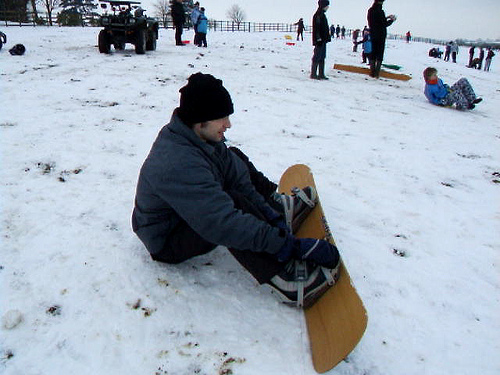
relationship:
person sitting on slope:
[312, 0, 344, 84] [5, 27, 495, 374]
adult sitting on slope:
[366, 0, 398, 81] [5, 27, 495, 374]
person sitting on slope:
[169, 2, 194, 48] [5, 27, 495, 374]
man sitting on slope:
[131, 70, 340, 310] [5, 27, 495, 374]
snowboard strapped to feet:
[261, 120, 380, 372] [269, 171, 338, 306]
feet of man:
[269, 171, 338, 306] [151, 73, 336, 345]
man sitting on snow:
[115, 56, 311, 281] [0, 24, 494, 370]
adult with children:
[164, 0, 200, 57] [192, 5, 212, 53]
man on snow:
[131, 70, 340, 310] [304, 132, 436, 306]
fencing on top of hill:
[9, 5, 351, 40] [1, 22, 494, 372]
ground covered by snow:
[0, 0, 498, 370] [0, 24, 494, 370]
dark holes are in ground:
[435, 176, 470, 204] [0, 0, 498, 370]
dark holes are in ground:
[390, 245, 408, 265] [0, 0, 498, 370]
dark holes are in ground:
[132, 293, 149, 315] [0, 0, 498, 370]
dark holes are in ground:
[48, 301, 64, 319] [0, 0, 498, 370]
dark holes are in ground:
[38, 160, 54, 179] [0, 0, 498, 370]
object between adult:
[333, 62, 410, 81] [366, 0, 391, 77]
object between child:
[333, 62, 410, 81] [351, 27, 370, 65]